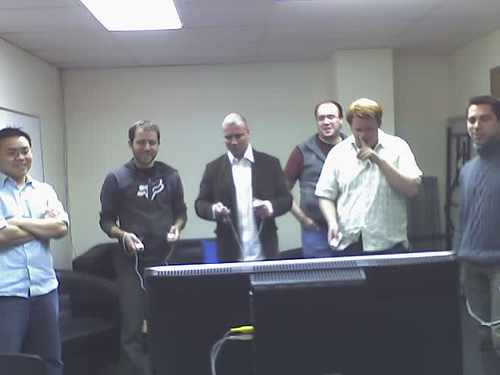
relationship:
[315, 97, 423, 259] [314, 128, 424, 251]
man wearing a shirt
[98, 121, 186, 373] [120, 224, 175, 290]
man holding controller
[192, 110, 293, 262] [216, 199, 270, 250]
man holding viedo controller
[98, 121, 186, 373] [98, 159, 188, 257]
man in hoodie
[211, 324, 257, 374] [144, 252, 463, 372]
cord in computer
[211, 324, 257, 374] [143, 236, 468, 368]
cord in computer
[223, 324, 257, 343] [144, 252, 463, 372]
cord in computer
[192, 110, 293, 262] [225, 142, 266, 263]
man wearing white shirt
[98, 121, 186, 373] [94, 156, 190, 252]
man wearing shirt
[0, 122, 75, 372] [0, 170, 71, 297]
man wearing shirt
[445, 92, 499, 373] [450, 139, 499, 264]
man wearing blue sweater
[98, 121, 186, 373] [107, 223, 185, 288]
man holding controller